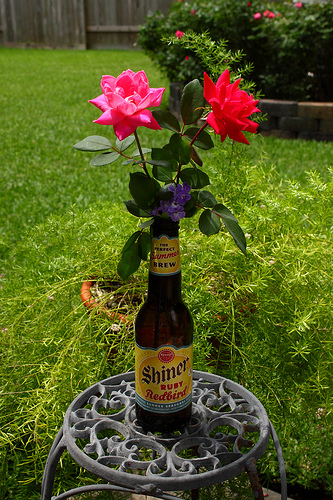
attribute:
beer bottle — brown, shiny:
[120, 222, 200, 433]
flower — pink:
[98, 63, 166, 194]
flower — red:
[185, 65, 263, 176]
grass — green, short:
[9, 53, 90, 136]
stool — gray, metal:
[30, 365, 287, 499]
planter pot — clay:
[228, 88, 333, 149]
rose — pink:
[94, 76, 175, 134]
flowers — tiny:
[152, 181, 197, 222]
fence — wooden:
[3, 7, 145, 49]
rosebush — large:
[182, 8, 331, 80]